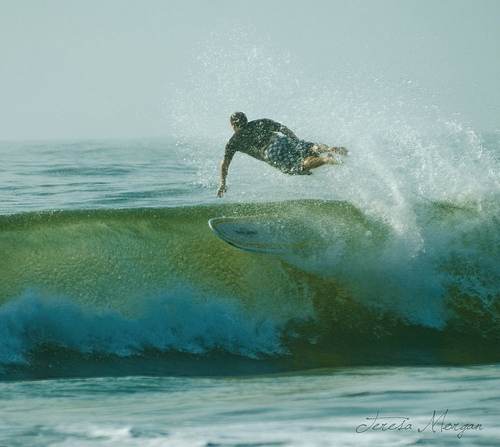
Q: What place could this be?
A: It is an ocean.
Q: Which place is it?
A: It is an ocean.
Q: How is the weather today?
A: It is cloudy.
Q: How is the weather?
A: It is cloudy.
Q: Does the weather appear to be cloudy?
A: Yes, it is cloudy.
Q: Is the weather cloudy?
A: Yes, it is cloudy.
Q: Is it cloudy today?
A: Yes, it is cloudy.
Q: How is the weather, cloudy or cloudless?
A: It is cloudy.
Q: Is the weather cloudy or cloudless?
A: It is cloudy.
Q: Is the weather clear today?
A: No, it is cloudy.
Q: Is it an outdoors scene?
A: Yes, it is outdoors.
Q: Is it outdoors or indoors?
A: It is outdoors.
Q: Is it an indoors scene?
A: No, it is outdoors.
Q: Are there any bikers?
A: No, there are no bikers.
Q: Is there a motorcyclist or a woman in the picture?
A: No, there are no bikers or women.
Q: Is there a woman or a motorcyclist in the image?
A: No, there are no bikers or women.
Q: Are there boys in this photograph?
A: No, there are no boys.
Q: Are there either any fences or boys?
A: No, there are no boys or fences.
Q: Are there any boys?
A: No, there are no boys.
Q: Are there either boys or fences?
A: No, there are no boys or fences.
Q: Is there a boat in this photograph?
A: No, there are no boats.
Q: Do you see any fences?
A: No, there are no fences.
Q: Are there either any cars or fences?
A: No, there are no fences or cars.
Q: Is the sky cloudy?
A: Yes, the sky is cloudy.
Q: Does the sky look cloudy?
A: Yes, the sky is cloudy.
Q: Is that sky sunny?
A: No, the sky is cloudy.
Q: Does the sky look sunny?
A: No, the sky is cloudy.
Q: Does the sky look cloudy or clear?
A: The sky is cloudy.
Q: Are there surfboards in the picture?
A: Yes, there is a surfboard.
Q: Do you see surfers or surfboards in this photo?
A: Yes, there is a surfboard.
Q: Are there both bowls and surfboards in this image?
A: No, there is a surfboard but no bowls.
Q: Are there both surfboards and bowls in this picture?
A: No, there is a surfboard but no bowls.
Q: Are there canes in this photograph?
A: No, there are no canes.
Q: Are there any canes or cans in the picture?
A: No, there are no canes or cans.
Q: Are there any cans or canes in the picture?
A: No, there are no canes or cans.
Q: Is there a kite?
A: No, there are no kites.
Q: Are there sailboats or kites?
A: No, there are no kites or sailboats.